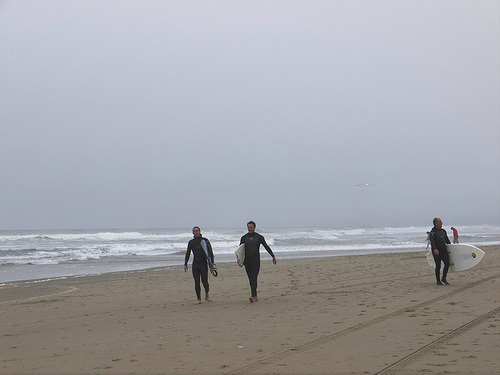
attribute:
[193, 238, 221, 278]
surfboard — blue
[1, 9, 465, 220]
sky — grey, hazy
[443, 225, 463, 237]
shirt — red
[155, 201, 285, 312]
surfers — walking together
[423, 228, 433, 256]
person — white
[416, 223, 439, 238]
head — bald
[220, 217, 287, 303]
man — in the middle, walking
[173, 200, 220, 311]
man — walking, on the left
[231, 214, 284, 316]
man — in the middle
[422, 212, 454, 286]
man — on the right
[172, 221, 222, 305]
man — on the left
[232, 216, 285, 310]
man — in the middle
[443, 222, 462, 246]
person — in the distance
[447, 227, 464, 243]
jacket — red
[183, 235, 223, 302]
suit — black, wet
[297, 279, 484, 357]
tracks — tire  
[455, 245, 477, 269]
emblem — blue 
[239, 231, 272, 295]
wetsuite — black 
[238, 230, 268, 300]
wetsuite — black 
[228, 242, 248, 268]
surfboard — Large white 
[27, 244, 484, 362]
beach — Section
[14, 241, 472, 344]
beach — Section 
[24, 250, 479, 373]
beach — Section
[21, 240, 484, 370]
beach — Section 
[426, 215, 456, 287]
surfer — bald